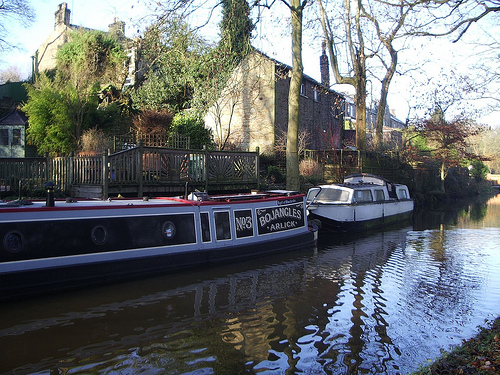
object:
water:
[2, 174, 499, 373]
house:
[200, 49, 344, 153]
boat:
[304, 173, 416, 233]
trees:
[276, 0, 453, 191]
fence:
[4, 146, 264, 196]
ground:
[277, 112, 394, 146]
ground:
[324, 180, 360, 218]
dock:
[4, 188, 306, 208]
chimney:
[52, 0, 73, 29]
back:
[387, 183, 416, 224]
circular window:
[60, 218, 131, 256]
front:
[0, 189, 315, 288]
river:
[30, 225, 482, 375]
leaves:
[132, 37, 218, 106]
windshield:
[307, 188, 349, 202]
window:
[353, 190, 374, 203]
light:
[300, 239, 499, 357]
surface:
[21, 221, 497, 367]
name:
[233, 207, 301, 232]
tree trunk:
[285, 2, 301, 193]